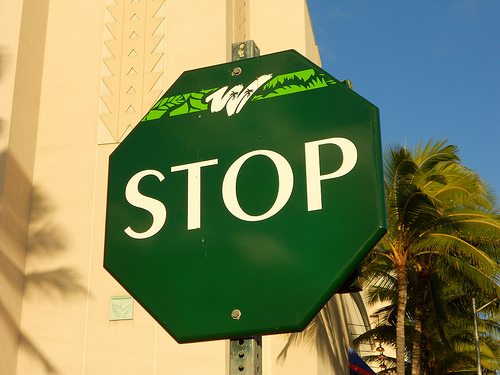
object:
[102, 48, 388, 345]
sign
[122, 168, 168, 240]
lettering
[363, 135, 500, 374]
tree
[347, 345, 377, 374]
triangle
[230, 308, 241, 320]
bolt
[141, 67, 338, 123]
logo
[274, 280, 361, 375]
shadow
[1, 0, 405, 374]
building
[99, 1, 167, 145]
design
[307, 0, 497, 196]
sky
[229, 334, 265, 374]
post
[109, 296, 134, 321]
switch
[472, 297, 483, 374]
light pole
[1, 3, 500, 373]
scene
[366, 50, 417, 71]
part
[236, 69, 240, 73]
part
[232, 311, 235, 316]
part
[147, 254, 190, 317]
part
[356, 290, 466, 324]
edge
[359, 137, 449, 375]
trees